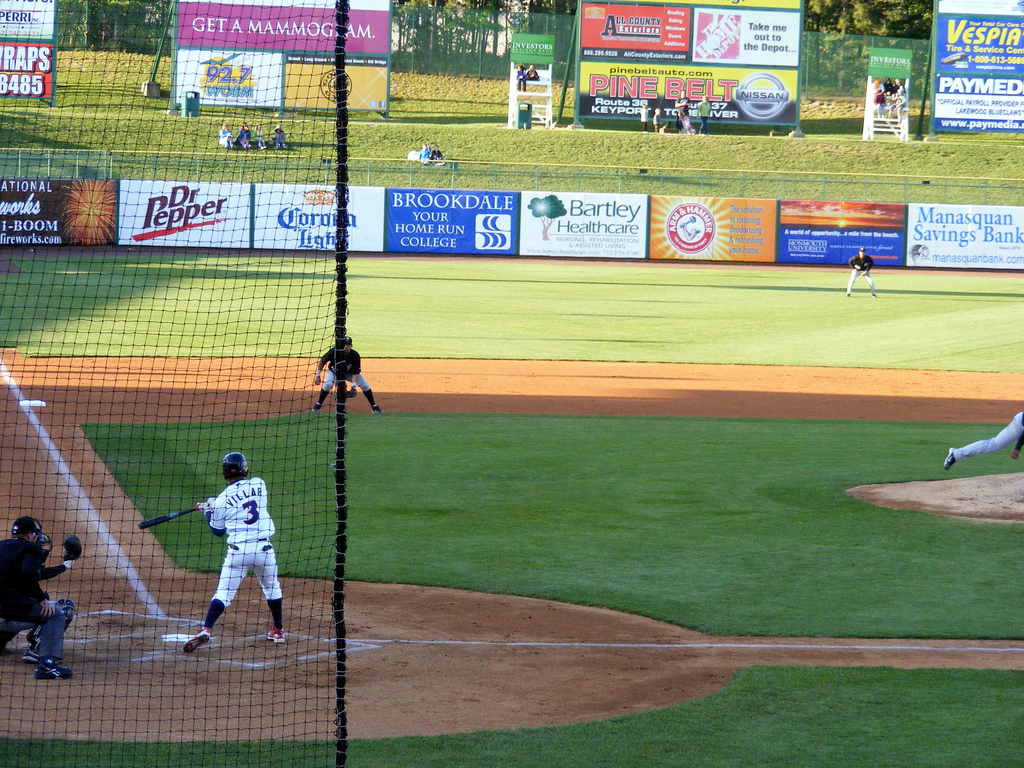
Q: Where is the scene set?
A: At the ballpark.